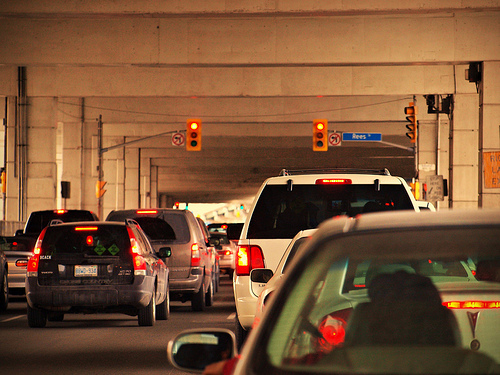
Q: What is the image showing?
A: It is showing a tunnel.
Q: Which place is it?
A: It is a tunnel.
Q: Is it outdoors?
A: Yes, it is outdoors.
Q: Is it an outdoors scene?
A: Yes, it is outdoors.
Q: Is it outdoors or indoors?
A: It is outdoors.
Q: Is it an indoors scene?
A: No, it is outdoors.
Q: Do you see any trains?
A: No, there are no trains.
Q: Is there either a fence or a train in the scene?
A: No, there are no trains or fences.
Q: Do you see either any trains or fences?
A: No, there are no trains or fences.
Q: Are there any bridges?
A: Yes, there is a bridge.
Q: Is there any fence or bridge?
A: Yes, there is a bridge.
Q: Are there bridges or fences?
A: Yes, there is a bridge.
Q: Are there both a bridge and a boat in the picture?
A: No, there is a bridge but no boats.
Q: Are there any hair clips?
A: No, there are no hair clips.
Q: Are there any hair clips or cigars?
A: No, there are no hair clips or cigars.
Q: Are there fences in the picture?
A: No, there are no fences.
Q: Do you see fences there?
A: No, there are no fences.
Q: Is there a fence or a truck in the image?
A: No, there are no fences or trucks.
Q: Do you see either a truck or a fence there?
A: No, there are no fences or trucks.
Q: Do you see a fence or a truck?
A: No, there are no fences or trucks.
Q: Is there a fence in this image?
A: No, there are no fences.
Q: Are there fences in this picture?
A: No, there are no fences.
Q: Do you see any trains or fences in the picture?
A: No, there are no fences or trains.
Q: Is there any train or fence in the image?
A: No, there are no fences or trains.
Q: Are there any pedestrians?
A: No, there are no pedestrians.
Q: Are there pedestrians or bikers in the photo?
A: No, there are no pedestrians or bikers.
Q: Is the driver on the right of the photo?
A: Yes, the driver is on the right of the image.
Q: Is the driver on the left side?
A: No, the driver is on the right of the image.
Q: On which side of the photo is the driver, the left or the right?
A: The driver is on the right of the image.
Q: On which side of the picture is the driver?
A: The driver is on the right of the image.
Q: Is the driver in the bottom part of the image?
A: Yes, the driver is in the bottom of the image.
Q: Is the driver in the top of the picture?
A: No, the driver is in the bottom of the image.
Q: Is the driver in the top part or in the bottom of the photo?
A: The driver is in the bottom of the image.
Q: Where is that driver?
A: The driver is in the car.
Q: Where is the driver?
A: The driver is in the car.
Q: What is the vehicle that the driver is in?
A: The vehicle is a car.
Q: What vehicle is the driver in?
A: The driver is in the car.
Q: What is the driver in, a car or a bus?
A: The driver is in a car.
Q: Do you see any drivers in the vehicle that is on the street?
A: Yes, there is a driver in the car.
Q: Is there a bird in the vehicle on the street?
A: No, there is a driver in the car.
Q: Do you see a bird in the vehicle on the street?
A: No, there is a driver in the car.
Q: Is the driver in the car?
A: Yes, the driver is in the car.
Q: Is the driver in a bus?
A: No, the driver is in the car.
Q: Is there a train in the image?
A: No, there are no trains.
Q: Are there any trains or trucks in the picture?
A: No, there are no trains or trucks.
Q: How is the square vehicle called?
A: The vehicle is a car.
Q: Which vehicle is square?
A: The vehicle is a car.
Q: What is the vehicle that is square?
A: The vehicle is a car.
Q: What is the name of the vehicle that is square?
A: The vehicle is a car.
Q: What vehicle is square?
A: The vehicle is a car.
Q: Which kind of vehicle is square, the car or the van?
A: The car is square.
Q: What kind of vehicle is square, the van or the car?
A: The car is square.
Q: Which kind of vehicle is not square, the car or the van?
A: The van is not square.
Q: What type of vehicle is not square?
A: The vehicle is a van.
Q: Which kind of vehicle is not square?
A: The vehicle is a van.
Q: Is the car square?
A: Yes, the car is square.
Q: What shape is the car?
A: The car is square.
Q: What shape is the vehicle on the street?
A: The car is square.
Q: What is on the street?
A: The car is on the street.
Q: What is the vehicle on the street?
A: The vehicle is a car.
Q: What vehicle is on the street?
A: The vehicle is a car.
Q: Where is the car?
A: The car is on the street.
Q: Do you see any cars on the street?
A: Yes, there is a car on the street.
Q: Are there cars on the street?
A: Yes, there is a car on the street.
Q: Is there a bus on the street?
A: No, there is a car on the street.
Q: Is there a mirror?
A: Yes, there is a mirror.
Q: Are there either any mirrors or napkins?
A: Yes, there is a mirror.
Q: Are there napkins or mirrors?
A: Yes, there is a mirror.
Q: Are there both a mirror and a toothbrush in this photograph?
A: No, there is a mirror but no toothbrushes.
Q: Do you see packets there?
A: No, there are no packets.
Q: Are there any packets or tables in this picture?
A: No, there are no packets or tables.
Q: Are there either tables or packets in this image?
A: No, there are no packets or tables.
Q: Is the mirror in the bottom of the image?
A: Yes, the mirror is in the bottom of the image.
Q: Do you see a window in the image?
A: Yes, there is a window.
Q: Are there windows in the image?
A: Yes, there is a window.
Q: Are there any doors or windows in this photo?
A: Yes, there is a window.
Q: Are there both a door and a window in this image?
A: No, there is a window but no doors.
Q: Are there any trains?
A: No, there are no trains.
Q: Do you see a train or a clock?
A: No, there are no trains or clocks.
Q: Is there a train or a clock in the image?
A: No, there are no trains or clocks.